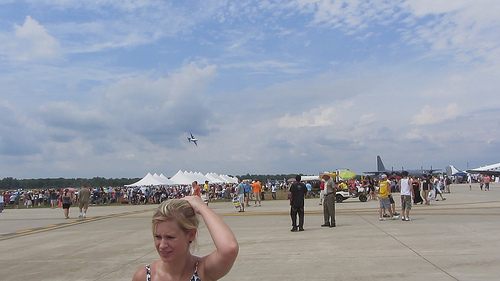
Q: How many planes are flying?
A: One.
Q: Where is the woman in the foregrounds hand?
A: On her head.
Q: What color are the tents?
A: White.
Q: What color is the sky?
A: Blue.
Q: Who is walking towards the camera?
A: The woman.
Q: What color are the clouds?
A: White.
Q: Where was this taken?
A: At an air show.